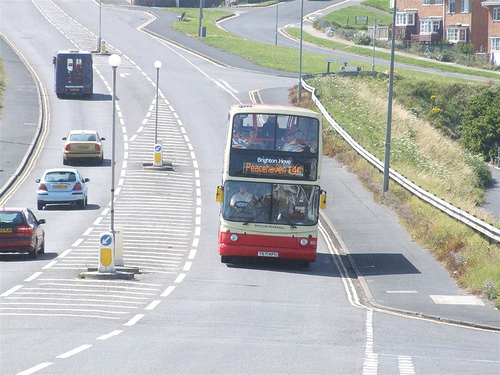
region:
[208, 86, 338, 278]
Double-decker bus running in the road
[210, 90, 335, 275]
Double-decker bus is white and red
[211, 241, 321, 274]
Bumper of double-decker bus is red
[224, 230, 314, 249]
Headlight on a red background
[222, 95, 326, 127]
Roof of the bus is white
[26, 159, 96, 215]
White car run in the road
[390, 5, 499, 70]
Buildings on the right side of road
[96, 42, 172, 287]
Light poles in the center of road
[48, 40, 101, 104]
Truck run in the road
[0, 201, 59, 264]
Red car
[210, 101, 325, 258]
this is a bus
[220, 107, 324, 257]
the bus is on motion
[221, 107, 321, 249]
the bus is double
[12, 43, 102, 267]
cars are on the other road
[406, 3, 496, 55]
a house is beside the road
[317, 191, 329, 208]
the bus has yellow side mirror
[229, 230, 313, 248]
the front lights are off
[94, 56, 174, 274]
lights are in the middle of the road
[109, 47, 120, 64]
the bulb is white in color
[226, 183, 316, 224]
the front screen is clear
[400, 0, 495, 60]
this is a building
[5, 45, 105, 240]
these are private cars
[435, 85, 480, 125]
the grass is green in color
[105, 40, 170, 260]
there are night lights on the road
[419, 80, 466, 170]
this is a lot of grass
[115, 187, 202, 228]
the road has white markings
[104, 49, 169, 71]
the bulbs are spherical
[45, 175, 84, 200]
the car is white in color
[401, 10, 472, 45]
these are some windows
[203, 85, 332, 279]
Double-decker bus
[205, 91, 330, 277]
Bus runs in the road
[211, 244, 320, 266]
Bumper of bus has a plate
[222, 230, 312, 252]
Headlights of bus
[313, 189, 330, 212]
Driver mirror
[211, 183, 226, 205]
Passenger mirror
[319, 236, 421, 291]
Shadow of bus cast in the road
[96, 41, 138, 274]
Pole on center of road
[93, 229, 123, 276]
Sign with a white arrow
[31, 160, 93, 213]
White car in motion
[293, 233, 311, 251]
left front headlight of a bus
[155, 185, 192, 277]
lines on a road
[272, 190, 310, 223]
left side of the lower front window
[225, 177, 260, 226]
ride side of the lower window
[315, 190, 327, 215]
left side mirror of the bus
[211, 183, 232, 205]
right side mirror of the bus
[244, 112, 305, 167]
upper window of the bus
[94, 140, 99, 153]
red indicator of a car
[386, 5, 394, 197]
a tall metal pole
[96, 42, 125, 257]
tall metal light post